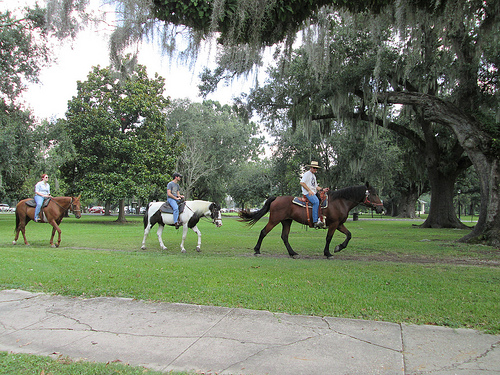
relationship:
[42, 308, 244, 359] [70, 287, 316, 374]
cracks in sidewalk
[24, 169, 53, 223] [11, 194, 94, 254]
woman riding horse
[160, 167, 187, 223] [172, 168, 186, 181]
man in cap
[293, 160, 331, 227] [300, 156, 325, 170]
man wearing hat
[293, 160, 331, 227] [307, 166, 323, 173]
man wears sunglasses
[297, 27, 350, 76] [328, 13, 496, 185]
moss in trees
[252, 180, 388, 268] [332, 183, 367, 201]
horse has black main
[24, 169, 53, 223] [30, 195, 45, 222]
woman wearing jeans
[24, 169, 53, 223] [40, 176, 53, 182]
woman wearing sunglasses